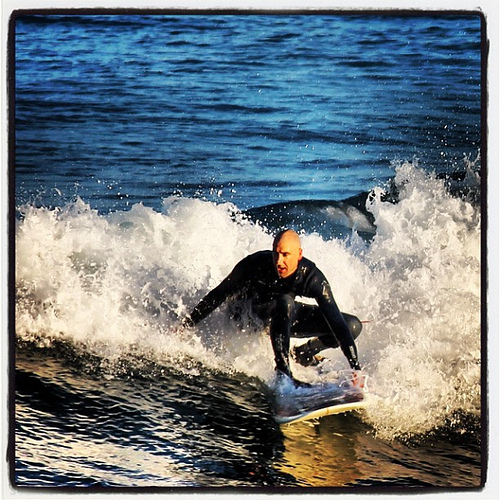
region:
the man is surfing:
[164, 205, 395, 499]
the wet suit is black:
[196, 243, 343, 396]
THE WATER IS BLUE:
[153, 42, 200, 92]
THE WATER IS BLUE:
[283, 117, 316, 142]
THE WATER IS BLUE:
[342, 124, 387, 154]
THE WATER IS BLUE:
[261, 160, 303, 185]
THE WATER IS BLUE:
[263, 48, 315, 118]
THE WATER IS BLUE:
[142, 32, 313, 107]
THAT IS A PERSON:
[187, 219, 372, 366]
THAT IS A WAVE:
[154, 207, 220, 277]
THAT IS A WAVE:
[390, 243, 471, 281]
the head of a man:
[247, 215, 356, 305]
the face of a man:
[259, 238, 311, 302]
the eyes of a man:
[270, 234, 310, 280]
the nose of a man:
[249, 239, 319, 287]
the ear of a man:
[280, 243, 324, 282]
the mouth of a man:
[262, 260, 311, 282]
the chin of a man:
[262, 263, 305, 289]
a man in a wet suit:
[225, 140, 382, 393]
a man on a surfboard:
[184, 178, 412, 450]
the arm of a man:
[156, 234, 293, 340]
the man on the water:
[167, 227, 366, 390]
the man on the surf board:
[180, 231, 366, 388]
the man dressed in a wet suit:
[164, 228, 365, 390]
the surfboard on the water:
[275, 385, 368, 420]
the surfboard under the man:
[270, 381, 370, 424]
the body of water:
[14, 13, 480, 485]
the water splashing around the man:
[16, 32, 481, 444]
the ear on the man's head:
[296, 247, 301, 259]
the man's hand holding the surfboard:
[351, 370, 364, 389]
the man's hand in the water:
[167, 322, 187, 336]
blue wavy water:
[25, 15, 478, 188]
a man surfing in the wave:
[179, 220, 369, 425]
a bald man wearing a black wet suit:
[171, 220, 379, 431]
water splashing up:
[18, 198, 195, 362]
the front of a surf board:
[275, 379, 369, 434]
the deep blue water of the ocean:
[26, 17, 468, 174]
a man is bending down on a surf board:
[171, 214, 383, 434]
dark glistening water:
[21, 348, 239, 483]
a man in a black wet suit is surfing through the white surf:
[180, 220, 387, 435]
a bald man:
[270, 224, 304, 280]